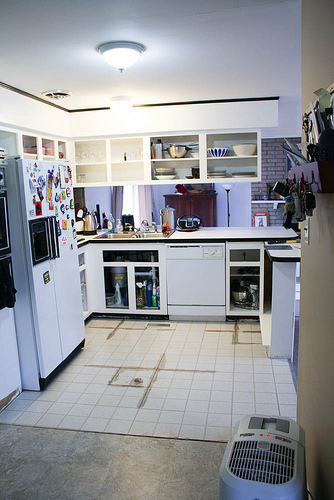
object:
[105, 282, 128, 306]
bottle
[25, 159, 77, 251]
magnets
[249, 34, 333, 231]
wall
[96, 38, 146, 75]
light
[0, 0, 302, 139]
ceiling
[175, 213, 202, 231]
radio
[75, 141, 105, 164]
glassware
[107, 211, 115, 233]
detergent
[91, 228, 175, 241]
sink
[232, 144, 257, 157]
bowl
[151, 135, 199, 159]
appliances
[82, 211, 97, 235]
coffeepot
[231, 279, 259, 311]
mixer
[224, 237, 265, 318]
cabinet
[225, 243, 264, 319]
shelf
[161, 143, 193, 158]
bowl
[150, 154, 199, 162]
shelf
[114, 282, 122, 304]
soap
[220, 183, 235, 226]
lamp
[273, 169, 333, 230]
rack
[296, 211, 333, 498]
wall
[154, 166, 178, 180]
dishes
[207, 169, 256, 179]
dishes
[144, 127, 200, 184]
cabinet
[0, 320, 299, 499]
floor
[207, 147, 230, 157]
bowl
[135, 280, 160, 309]
cleaning products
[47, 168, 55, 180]
clip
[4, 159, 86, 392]
fridge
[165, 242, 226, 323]
dishwasher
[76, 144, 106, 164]
wine glasses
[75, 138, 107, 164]
shelf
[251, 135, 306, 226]
brick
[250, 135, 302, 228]
brick wall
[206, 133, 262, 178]
cabinet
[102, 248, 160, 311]
cabinet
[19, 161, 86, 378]
refrigerator door